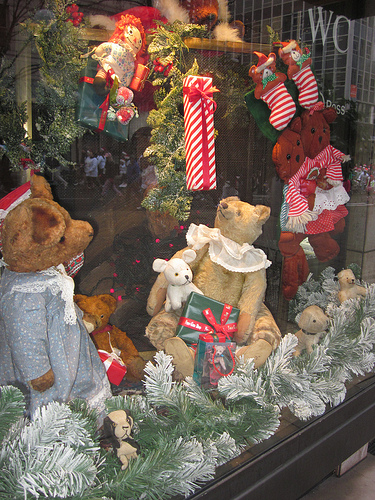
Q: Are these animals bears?
A: No, there are both dogs and bears.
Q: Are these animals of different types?
A: Yes, they are dogs and bears.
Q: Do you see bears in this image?
A: Yes, there is a bear.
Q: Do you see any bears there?
A: Yes, there is a bear.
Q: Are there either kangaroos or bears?
A: Yes, there is a bear.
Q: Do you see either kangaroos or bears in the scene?
A: Yes, there is a bear.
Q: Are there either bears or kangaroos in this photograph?
A: Yes, there is a bear.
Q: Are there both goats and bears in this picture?
A: No, there is a bear but no goats.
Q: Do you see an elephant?
A: No, there are no elephants.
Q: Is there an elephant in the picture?
A: No, there are no elephants.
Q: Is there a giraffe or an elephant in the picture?
A: No, there are no elephants or giraffes.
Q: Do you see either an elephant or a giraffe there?
A: No, there are no elephants or giraffes.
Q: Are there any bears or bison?
A: Yes, there is a bear.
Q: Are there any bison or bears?
A: Yes, there is a bear.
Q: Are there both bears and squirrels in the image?
A: No, there is a bear but no squirrels.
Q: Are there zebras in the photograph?
A: No, there are no zebras.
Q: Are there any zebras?
A: No, there are no zebras.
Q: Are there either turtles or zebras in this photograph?
A: No, there are no zebras or turtles.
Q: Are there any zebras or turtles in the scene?
A: No, there are no zebras or turtles.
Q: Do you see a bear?
A: Yes, there is a bear.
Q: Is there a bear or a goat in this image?
A: Yes, there is a bear.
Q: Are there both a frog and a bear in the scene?
A: No, there is a bear but no frogs.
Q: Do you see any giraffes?
A: No, there are no giraffes.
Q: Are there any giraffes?
A: No, there are no giraffes.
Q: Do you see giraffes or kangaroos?
A: No, there are no giraffes or kangaroos.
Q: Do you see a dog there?
A: Yes, there is a dog.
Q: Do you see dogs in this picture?
A: Yes, there is a dog.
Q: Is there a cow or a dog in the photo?
A: Yes, there is a dog.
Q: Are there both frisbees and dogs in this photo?
A: No, there is a dog but no frisbees.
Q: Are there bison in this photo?
A: No, there are no bison.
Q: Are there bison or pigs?
A: No, there are no bison or pigs.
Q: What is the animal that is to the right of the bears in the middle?
A: The animal is a dog.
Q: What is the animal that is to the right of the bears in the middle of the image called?
A: The animal is a dog.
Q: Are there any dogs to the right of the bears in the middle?
A: Yes, there is a dog to the right of the bears.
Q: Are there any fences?
A: No, there are no fences.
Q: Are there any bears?
A: Yes, there is a bear.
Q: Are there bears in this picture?
A: Yes, there is a bear.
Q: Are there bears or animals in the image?
A: Yes, there is a bear.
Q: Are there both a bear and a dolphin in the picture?
A: No, there is a bear but no dolphins.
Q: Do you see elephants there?
A: No, there are no elephants.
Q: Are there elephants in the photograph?
A: No, there are no elephants.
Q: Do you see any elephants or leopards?
A: No, there are no elephants or leopards.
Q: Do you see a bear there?
A: Yes, there is a bear.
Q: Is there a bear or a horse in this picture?
A: Yes, there is a bear.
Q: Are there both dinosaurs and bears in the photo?
A: No, there is a bear but no dinosaurs.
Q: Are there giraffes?
A: No, there are no giraffes.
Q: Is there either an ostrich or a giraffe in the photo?
A: No, there are no giraffes or ostriches.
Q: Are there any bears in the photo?
A: Yes, there is a bear.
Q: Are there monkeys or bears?
A: Yes, there is a bear.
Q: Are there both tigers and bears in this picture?
A: No, there is a bear but no tigers.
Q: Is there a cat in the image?
A: No, there are no cats.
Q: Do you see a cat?
A: No, there are no cats.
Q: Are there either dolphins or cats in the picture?
A: No, there are no cats or dolphins.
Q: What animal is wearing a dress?
A: The animal is a bear.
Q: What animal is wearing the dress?
A: The animal is a bear.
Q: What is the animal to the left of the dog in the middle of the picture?
A: The animal is a bear.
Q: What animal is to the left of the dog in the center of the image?
A: The animal is a bear.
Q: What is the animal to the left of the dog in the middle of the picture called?
A: The animal is a bear.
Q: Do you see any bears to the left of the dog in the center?
A: Yes, there is a bear to the left of the dog.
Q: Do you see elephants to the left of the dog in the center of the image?
A: No, there is a bear to the left of the dog.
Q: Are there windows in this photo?
A: Yes, there is a window.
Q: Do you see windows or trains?
A: Yes, there is a window.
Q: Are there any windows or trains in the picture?
A: Yes, there is a window.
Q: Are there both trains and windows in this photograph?
A: No, there is a window but no trains.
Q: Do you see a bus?
A: No, there are no buses.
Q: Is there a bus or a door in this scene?
A: No, there are no buses or doors.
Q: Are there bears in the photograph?
A: Yes, there are bears.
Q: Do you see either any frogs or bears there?
A: Yes, there are bears.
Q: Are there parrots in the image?
A: No, there are no parrots.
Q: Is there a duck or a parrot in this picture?
A: No, there are no parrots or ducks.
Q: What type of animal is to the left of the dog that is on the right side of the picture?
A: The animals are bears.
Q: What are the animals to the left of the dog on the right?
A: The animals are bears.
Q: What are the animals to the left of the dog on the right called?
A: The animals are bears.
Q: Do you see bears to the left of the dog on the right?
A: Yes, there are bears to the left of the dog.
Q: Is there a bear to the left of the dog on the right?
A: Yes, there are bears to the left of the dog.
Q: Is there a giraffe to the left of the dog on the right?
A: No, there are bears to the left of the dog.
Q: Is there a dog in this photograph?
A: Yes, there is a dog.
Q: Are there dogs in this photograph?
A: Yes, there is a dog.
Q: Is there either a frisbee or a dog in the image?
A: Yes, there is a dog.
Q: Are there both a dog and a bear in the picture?
A: Yes, there are both a dog and a bear.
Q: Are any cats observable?
A: No, there are no cats.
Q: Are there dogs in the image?
A: Yes, there is a dog.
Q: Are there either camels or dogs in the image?
A: Yes, there is a dog.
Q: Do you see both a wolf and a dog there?
A: No, there is a dog but no wolves.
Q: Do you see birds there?
A: No, there are no birds.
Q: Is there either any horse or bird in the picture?
A: No, there are no birds or horses.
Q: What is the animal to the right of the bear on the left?
A: The animal is a dog.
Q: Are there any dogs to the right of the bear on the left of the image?
A: Yes, there is a dog to the right of the bear.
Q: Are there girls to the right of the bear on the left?
A: No, there is a dog to the right of the bear.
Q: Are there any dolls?
A: Yes, there is a doll.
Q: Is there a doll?
A: Yes, there is a doll.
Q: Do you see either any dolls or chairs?
A: Yes, there is a doll.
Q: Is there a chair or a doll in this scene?
A: Yes, there is a doll.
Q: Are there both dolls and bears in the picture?
A: Yes, there are both a doll and a bear.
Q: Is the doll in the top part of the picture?
A: Yes, the doll is in the top of the image.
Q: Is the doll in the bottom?
A: No, the doll is in the top of the image.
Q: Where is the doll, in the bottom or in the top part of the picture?
A: The doll is in the top of the image.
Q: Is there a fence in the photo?
A: No, there are no fences.